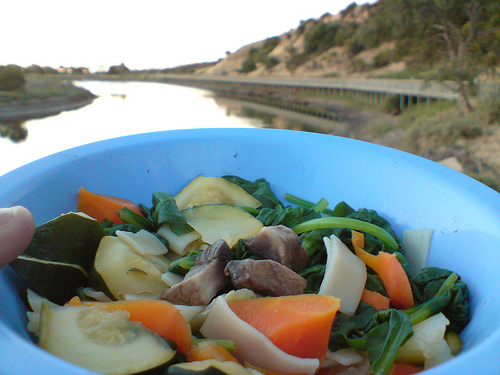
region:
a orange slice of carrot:
[227, 296, 334, 350]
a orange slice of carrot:
[64, 293, 236, 362]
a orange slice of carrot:
[76, 186, 138, 216]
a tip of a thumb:
[1, 205, 28, 265]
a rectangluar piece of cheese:
[196, 297, 318, 372]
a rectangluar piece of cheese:
[317, 229, 361, 301]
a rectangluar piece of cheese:
[121, 232, 161, 251]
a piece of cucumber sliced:
[40, 301, 167, 363]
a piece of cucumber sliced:
[95, 236, 169, 295]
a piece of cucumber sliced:
[183, 205, 258, 251]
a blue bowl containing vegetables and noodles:
[3, 121, 498, 372]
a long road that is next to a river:
[162, 66, 476, 120]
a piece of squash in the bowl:
[36, 305, 189, 371]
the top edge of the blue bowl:
[29, 118, 394, 178]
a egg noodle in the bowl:
[317, 231, 368, 318]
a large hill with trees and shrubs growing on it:
[219, 4, 497, 76]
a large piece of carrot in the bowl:
[238, 297, 346, 355]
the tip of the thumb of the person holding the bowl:
[5, 203, 35, 265]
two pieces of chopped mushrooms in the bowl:
[221, 218, 311, 292]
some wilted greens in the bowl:
[412, 268, 475, 324]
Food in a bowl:
[23, 120, 453, 371]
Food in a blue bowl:
[25, 124, 456, 355]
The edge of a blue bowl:
[96, 117, 316, 166]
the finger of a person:
[3, 188, 41, 278]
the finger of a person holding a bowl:
[4, 143, 44, 271]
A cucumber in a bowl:
[32, 277, 175, 372]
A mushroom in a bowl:
[177, 220, 254, 323]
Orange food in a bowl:
[219, 278, 355, 356]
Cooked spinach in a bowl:
[372, 243, 465, 327]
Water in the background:
[77, 75, 235, 183]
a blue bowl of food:
[0, 122, 499, 374]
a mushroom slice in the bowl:
[226, 257, 311, 297]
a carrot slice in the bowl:
[228, 290, 339, 362]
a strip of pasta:
[196, 290, 323, 373]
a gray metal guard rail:
[160, 69, 499, 119]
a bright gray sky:
[0, 0, 377, 70]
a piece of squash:
[34, 300, 176, 372]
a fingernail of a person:
[0, 201, 17, 228]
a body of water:
[0, 76, 352, 180]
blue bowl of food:
[0, 125, 497, 373]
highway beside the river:
[125, 58, 459, 103]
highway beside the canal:
[142, 57, 459, 107]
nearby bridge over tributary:
[383, 70, 471, 130]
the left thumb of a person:
[0, 193, 50, 260]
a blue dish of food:
[1, 129, 496, 373]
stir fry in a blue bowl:
[2, 144, 498, 374]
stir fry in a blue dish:
[29, 155, 485, 374]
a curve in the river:
[27, 65, 197, 115]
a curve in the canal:
[41, 42, 214, 117]